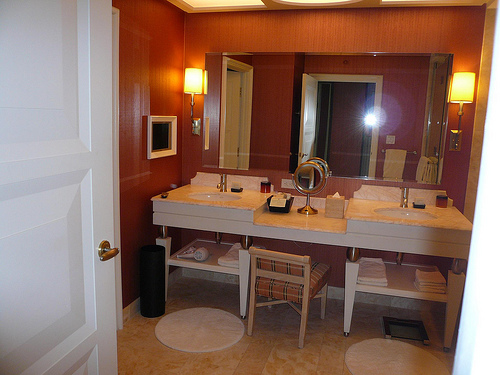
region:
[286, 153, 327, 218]
mirror on bathroom counter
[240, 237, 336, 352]
chair in front of bathroom counter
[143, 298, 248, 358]
round white rug in front of bathroom counter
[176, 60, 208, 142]
wall lamp mounted on wall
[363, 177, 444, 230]
sink and faucet on bathroom counter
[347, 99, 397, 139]
white spotlight on wall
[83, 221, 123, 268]
metal door handle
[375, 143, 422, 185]
white towel on rack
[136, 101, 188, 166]
white framed mirror on wall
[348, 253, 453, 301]
white folded towels underneath bathroom sink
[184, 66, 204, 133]
A lamp on a wall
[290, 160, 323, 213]
A silver mirror on a sink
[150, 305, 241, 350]
A circular white rug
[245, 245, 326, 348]
A brown chair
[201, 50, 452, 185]
A rectangular mirror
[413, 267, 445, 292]
A stack of small towels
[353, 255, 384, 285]
A stack of larger towels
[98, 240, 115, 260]
A door knob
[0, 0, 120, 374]
A white door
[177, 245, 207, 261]
A white hair dryer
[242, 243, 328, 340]
a tan chair under counter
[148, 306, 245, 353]
a white round rug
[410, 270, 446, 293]
a stack of white towels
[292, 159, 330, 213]
a gold mirror on a sink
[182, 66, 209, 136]
gold lamps on the wall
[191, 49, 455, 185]
a square mirror on a wall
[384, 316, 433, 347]
silver scale on a floor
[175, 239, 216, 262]
a white hair dryer on a shelf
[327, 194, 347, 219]
a tan tissue box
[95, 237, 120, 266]
a gold door handle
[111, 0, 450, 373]
A bathroom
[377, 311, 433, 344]
A scale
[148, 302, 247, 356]
A round rug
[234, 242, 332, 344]
A small wooden chair with cushions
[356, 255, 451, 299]
White towels folded in stacks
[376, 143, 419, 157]
A silver towel rack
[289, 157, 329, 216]
A round mirror with a silver base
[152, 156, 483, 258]
A double sink in a bathroom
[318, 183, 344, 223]
A box of tissues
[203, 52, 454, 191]
A large bathroom mirror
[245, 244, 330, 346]
A chair by the sinks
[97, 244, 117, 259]
A handle on the door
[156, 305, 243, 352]
A circular rug beneath the sink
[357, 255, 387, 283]
A towel beneath the sink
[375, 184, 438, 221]
A sink on the counter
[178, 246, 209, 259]
A blow dryer on the shelf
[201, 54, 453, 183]
A mirror on the wall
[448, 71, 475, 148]
A lamp on the wall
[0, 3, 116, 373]
A door leading into the room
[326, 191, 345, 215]
A box of tissues